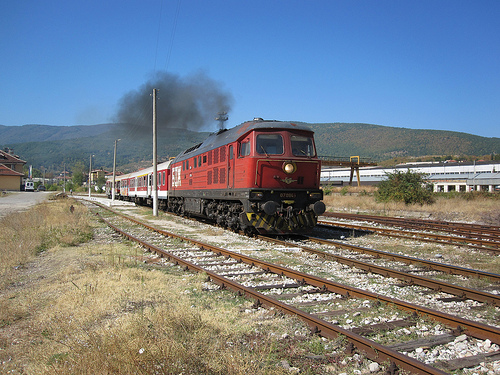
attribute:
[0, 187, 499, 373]
grass — brown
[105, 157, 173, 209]
train car — red, white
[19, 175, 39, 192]
van — parked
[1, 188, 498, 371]
dead grass — dry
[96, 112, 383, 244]
passenger train — old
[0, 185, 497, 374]
grassy ground — dried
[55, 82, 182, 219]
lamp posts — tall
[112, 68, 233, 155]
smoke — black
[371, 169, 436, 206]
bush — green, small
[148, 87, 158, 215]
pole — tall, metal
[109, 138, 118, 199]
pole — tall, metal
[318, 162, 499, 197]
buildings — white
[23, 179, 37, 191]
van — white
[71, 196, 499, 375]
rails — brown, steel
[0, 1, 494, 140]
sky — blue, clear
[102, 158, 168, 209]
train — white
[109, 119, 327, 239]
train — red, white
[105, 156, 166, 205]
cars — red